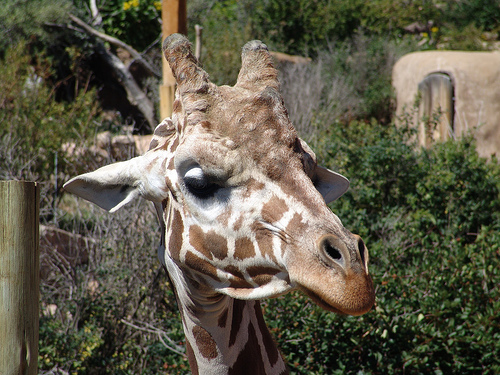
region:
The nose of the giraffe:
[316, 235, 370, 266]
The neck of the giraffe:
[175, 306, 280, 369]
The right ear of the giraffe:
[60, 161, 165, 201]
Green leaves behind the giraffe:
[439, 235, 493, 344]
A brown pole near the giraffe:
[0, 182, 36, 374]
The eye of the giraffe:
[182, 162, 219, 199]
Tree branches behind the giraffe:
[106, 51, 155, 112]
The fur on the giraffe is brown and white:
[172, 237, 244, 269]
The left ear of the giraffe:
[304, 160, 351, 197]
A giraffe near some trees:
[58, 33, 380, 371]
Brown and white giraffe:
[55, 37, 405, 356]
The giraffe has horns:
[141, 19, 297, 136]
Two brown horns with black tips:
[140, 19, 296, 130]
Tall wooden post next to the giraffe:
[1, 174, 53, 366]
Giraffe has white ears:
[56, 134, 156, 221]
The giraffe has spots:
[75, 30, 385, 355]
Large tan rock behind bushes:
[383, 31, 497, 162]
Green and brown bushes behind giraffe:
[46, 71, 494, 369]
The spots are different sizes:
[55, 37, 390, 364]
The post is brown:
[148, 3, 189, 118]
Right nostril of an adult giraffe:
[320, 235, 350, 266]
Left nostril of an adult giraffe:
[350, 231, 375, 266]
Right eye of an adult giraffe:
[180, 163, 227, 209]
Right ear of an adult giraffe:
[55, 158, 172, 225]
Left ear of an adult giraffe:
[300, 140, 367, 203]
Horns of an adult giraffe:
[158, 27, 288, 102]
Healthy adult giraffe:
[45, 27, 405, 333]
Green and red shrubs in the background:
[381, 158, 482, 368]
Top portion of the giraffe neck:
[170, 295, 290, 371]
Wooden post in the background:
[2, 173, 42, 374]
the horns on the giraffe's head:
[165, 30, 276, 85]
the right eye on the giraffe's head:
[180, 165, 225, 200]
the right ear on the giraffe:
[55, 145, 155, 210]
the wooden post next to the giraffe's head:
[0, 176, 40, 371]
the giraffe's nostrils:
[317, 230, 370, 276]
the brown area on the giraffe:
[240, 346, 260, 371]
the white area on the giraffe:
[196, 356, 221, 371]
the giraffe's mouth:
[290, 275, 377, 316]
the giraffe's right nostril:
[317, 235, 348, 277]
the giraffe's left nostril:
[354, 233, 366, 275]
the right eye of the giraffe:
[178, 154, 218, 202]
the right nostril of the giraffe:
[312, 225, 347, 270]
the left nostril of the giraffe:
[347, 230, 376, 274]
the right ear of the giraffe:
[55, 148, 175, 218]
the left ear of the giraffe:
[292, 139, 354, 209]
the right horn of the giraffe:
[157, 28, 217, 111]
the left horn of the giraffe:
[233, 37, 282, 96]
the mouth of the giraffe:
[292, 277, 380, 317]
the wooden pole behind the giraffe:
[155, 3, 195, 123]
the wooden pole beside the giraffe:
[0, 174, 47, 374]